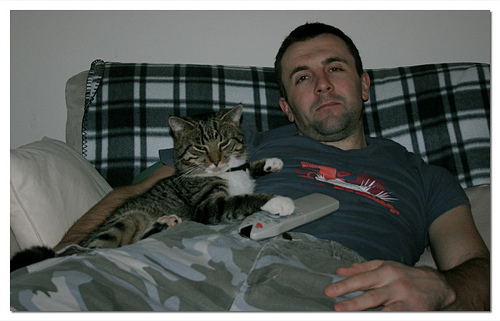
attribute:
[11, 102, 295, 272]
cat — black, white, striped, lying down, lying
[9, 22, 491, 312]
man — lying down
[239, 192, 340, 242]
remote — gray, grey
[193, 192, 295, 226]
paw — white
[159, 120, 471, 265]
shirt — short sleeved, black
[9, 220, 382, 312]
pants — camouflage, camo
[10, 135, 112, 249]
pillow — white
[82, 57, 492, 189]
blanket — striped, black, white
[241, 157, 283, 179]
paw — white